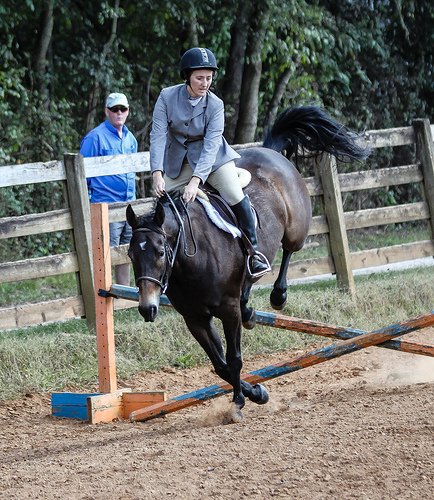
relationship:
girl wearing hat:
[150, 49, 265, 273] [177, 45, 217, 84]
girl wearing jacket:
[150, 46, 267, 272] [150, 83, 236, 185]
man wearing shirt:
[78, 91, 139, 287] [72, 123, 150, 202]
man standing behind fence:
[78, 91, 139, 287] [0, 119, 432, 347]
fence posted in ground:
[0, 118, 433, 337] [0, 313, 419, 498]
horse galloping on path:
[124, 104, 372, 426] [233, 430, 377, 492]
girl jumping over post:
[150, 46, 267, 272] [46, 203, 420, 426]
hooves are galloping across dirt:
[216, 287, 290, 429] [2, 346, 420, 484]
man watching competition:
[80, 91, 131, 311] [135, 33, 411, 489]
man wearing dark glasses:
[78, 91, 139, 287] [107, 104, 128, 112]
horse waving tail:
[116, 99, 381, 425] [264, 97, 374, 172]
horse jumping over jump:
[116, 99, 381, 425] [51, 202, 432, 421]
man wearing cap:
[78, 91, 139, 287] [105, 92, 129, 108]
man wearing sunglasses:
[78, 91, 139, 287] [107, 103, 129, 114]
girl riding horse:
[150, 46, 267, 272] [116, 99, 381, 425]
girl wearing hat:
[150, 46, 267, 272] [179, 47, 218, 79]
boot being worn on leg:
[221, 190, 320, 285] [203, 159, 259, 256]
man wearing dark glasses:
[78, 91, 139, 287] [105, 106, 129, 112]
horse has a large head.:
[124, 104, 372, 426] [119, 202, 182, 323]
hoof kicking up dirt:
[225, 404, 247, 418] [195, 396, 243, 427]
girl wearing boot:
[150, 46, 267, 272] [225, 192, 267, 273]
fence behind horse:
[6, 113, 432, 329] [116, 99, 381, 425]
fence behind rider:
[6, 113, 432, 329] [148, 38, 272, 287]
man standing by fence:
[78, 91, 139, 287] [310, 125, 431, 270]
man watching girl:
[78, 91, 139, 287] [150, 46, 267, 272]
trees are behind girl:
[140, 1, 402, 126] [150, 46, 267, 272]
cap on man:
[102, 92, 129, 111] [78, 91, 139, 287]